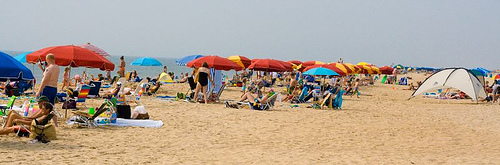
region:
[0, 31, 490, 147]
The people are on a beach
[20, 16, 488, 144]
Some people are using nice umbrellas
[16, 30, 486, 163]
Some people are close to the water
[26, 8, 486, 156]
Some people are on their vacation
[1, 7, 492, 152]
Some people are enjoying the sunshine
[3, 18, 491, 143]
Some people have brought their families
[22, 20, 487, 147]
Some people are enjoying the day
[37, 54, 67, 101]
man in blue shorts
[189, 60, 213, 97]
woman in black swimsuit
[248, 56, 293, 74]
red umbrella on beach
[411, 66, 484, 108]
white tent on beach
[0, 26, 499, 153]
people on a beach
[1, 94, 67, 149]
couple sitting in chairs at beach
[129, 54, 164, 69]
light blue umbrella on beach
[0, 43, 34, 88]
dark blue umbrella on beach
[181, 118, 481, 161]
sand at the beach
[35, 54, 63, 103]
man in blue shorts with tattoo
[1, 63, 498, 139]
the people are at the beach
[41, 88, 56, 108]
the man wears shorts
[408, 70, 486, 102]
the person is under a tent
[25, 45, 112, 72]
the umbrella is red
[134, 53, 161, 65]
the umbrella is blue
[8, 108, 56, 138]
the woman is on a chair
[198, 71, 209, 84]
the woman wears black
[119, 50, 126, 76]
the person is standing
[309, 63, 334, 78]
Blue umbrella on beach.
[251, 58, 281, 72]
Red umbrella on beach.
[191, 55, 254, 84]
Red umbrella on beach.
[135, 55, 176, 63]
Blue umbrella on beach.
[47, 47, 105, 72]
Red umbrella on beach.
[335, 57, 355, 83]
Red and yellow umbrella on beach.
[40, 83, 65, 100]
Person wearing blue shorts.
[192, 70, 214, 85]
Person wearing black swimming suit.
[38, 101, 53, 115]
Person has dark hair.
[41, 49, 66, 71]
the head of a man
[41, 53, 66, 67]
the hair of a man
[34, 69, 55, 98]
the arm of a man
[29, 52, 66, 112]
the body of a man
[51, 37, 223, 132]
people on the beach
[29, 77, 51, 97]
the hand of a man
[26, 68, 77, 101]
a man with no shirt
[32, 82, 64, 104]
a man wearing shorts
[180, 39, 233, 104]
the back of a woman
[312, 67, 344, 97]
an open large umbrella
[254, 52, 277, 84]
an open large umbrella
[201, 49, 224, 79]
an open large umbrella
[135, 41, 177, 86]
an open large umbrella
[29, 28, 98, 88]
an open large umbrella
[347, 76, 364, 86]
an open large umbrella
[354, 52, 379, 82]
an open large umbrella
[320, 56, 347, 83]
an open large umbrella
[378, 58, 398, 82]
an open large umbrella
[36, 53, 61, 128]
A person is standing up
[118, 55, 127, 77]
A person is standing up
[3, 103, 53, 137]
A person sitting down.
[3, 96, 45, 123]
A person is sitting down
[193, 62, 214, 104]
A person is standing up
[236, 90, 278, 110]
A person sitting down.